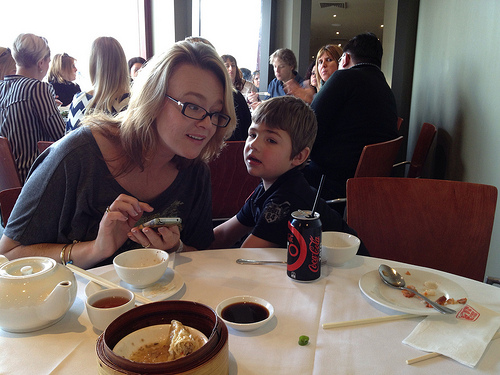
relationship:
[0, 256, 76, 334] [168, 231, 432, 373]
tea kettle on table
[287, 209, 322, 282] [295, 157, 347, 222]
can with straw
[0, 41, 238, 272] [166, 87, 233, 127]
person with glasses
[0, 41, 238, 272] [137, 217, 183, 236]
person holding cell phone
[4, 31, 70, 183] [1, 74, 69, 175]
woman with shirt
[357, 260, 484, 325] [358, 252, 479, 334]
plate with spoon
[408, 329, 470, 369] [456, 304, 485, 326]
napkin with writing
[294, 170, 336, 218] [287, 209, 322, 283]
straw in can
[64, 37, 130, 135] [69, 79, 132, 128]
person in shirt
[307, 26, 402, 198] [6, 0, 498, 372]
person eating restaurant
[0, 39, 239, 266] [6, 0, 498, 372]
person eating at restaurant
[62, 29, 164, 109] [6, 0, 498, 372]
person eating at restaurant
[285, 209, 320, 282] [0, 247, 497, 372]
soda on table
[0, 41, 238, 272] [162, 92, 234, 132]
person has glasses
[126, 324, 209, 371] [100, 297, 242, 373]
food in dish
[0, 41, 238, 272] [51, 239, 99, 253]
person has bracelet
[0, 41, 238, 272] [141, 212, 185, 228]
person holding cell phone